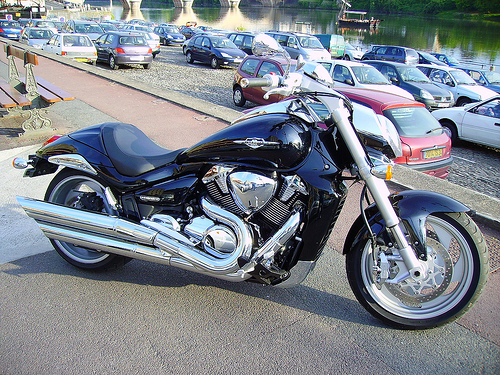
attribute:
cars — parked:
[97, 15, 447, 188]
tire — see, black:
[353, 184, 481, 316]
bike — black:
[51, 97, 463, 329]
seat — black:
[103, 121, 214, 184]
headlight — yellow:
[368, 135, 414, 201]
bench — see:
[16, 51, 83, 109]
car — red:
[336, 79, 452, 159]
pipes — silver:
[10, 183, 240, 285]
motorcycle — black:
[57, 15, 488, 319]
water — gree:
[378, 13, 457, 52]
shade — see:
[259, 240, 380, 343]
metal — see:
[197, 156, 295, 254]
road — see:
[74, 71, 180, 136]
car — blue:
[180, 32, 257, 67]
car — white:
[35, 24, 98, 70]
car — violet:
[87, 30, 159, 69]